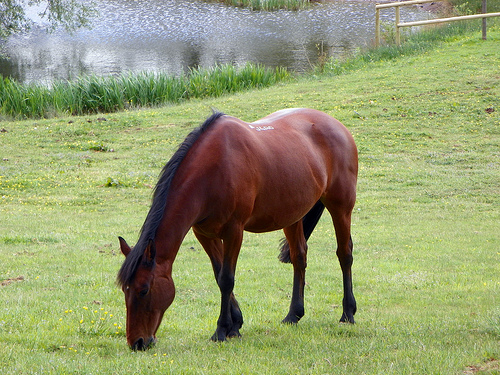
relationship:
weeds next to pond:
[0, 62, 291, 121] [0, 0, 440, 84]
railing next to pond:
[374, 0, 499, 54] [0, 0, 440, 84]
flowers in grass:
[57, 304, 175, 369] [0, 16, 499, 374]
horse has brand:
[114, 105, 360, 352] [248, 123, 274, 131]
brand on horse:
[248, 123, 274, 131] [114, 105, 360, 352]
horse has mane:
[114, 105, 360, 352] [117, 109, 222, 286]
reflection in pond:
[22, 52, 120, 80] [0, 0, 440, 84]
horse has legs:
[114, 105, 360, 352] [195, 180, 357, 341]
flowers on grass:
[57, 304, 175, 369] [0, 16, 499, 374]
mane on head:
[117, 109, 222, 286] [122, 249, 176, 351]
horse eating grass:
[114, 105, 360, 352] [0, 16, 499, 374]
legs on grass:
[195, 180, 357, 341] [0, 16, 499, 374]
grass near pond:
[0, 16, 499, 374] [0, 0, 440, 84]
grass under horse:
[0, 16, 499, 374] [114, 105, 360, 352]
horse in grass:
[114, 105, 360, 352] [0, 16, 499, 374]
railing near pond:
[374, 0, 499, 54] [0, 0, 440, 84]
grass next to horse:
[0, 16, 499, 374] [114, 105, 360, 352]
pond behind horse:
[0, 0, 440, 84] [114, 105, 360, 352]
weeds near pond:
[0, 62, 291, 121] [0, 0, 440, 84]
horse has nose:
[114, 105, 360, 352] [129, 335, 158, 349]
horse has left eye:
[114, 105, 360, 352] [139, 288, 148, 297]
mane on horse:
[117, 109, 222, 286] [114, 105, 360, 352]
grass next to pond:
[0, 16, 499, 374] [0, 0, 440, 84]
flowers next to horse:
[57, 304, 175, 369] [114, 105, 360, 352]